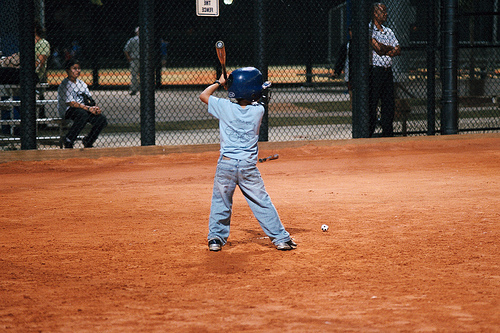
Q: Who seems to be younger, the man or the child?
A: The child is younger than the man.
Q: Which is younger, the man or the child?
A: The child is younger than the man.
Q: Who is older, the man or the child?
A: The man is older than the child.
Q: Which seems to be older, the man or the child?
A: The man is older than the child.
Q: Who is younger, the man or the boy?
A: The boy is younger than the man.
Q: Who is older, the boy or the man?
A: The man is older than the boy.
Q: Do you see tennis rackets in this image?
A: No, there are no tennis rackets.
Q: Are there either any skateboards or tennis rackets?
A: No, there are no tennis rackets or skateboards.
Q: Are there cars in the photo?
A: No, there are no cars.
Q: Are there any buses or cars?
A: No, there are no cars or buses.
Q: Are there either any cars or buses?
A: No, there are no cars or buses.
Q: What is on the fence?
A: The sign is on the fence.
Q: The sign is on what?
A: The sign is on the fence.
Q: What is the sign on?
A: The sign is on the fence.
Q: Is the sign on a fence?
A: Yes, the sign is on a fence.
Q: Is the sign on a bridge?
A: No, the sign is on a fence.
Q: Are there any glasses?
A: No, there are no glasses.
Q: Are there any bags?
A: No, there are no bags.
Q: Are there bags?
A: No, there are no bags.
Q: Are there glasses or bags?
A: No, there are no bags or glasses.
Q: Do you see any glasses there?
A: No, there are no glasses.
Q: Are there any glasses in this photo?
A: No, there are no glasses.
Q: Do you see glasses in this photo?
A: No, there are no glasses.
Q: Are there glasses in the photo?
A: No, there are no glasses.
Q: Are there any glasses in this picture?
A: No, there are no glasses.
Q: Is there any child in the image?
A: Yes, there is a child.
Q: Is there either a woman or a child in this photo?
A: Yes, there is a child.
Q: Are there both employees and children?
A: No, there is a child but no employees.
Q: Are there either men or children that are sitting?
A: Yes, the child is sitting.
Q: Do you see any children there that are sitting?
A: Yes, there is a child that is sitting.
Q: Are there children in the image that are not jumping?
A: Yes, there is a child that is sitting.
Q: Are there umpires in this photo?
A: No, there are no umpires.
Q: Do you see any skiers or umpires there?
A: No, there are no umpires or skiers.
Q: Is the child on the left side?
A: Yes, the child is on the left of the image.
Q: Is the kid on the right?
A: No, the kid is on the left of the image.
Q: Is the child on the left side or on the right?
A: The child is on the left of the image.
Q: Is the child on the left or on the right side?
A: The child is on the left of the image.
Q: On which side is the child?
A: The child is on the left of the image.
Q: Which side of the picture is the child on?
A: The child is on the left of the image.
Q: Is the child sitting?
A: Yes, the child is sitting.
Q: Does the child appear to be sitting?
A: Yes, the child is sitting.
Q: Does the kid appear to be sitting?
A: Yes, the kid is sitting.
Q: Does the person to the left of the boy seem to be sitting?
A: Yes, the kid is sitting.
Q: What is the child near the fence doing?
A: The kid is sitting.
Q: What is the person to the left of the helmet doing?
A: The kid is sitting.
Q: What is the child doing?
A: The kid is sitting.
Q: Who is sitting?
A: The kid is sitting.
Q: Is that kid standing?
A: No, the kid is sitting.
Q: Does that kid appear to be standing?
A: No, the kid is sitting.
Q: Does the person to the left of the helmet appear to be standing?
A: No, the kid is sitting.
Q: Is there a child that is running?
A: No, there is a child but he is sitting.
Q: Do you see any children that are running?
A: No, there is a child but he is sitting.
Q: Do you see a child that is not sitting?
A: No, there is a child but he is sitting.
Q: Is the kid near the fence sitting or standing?
A: The kid is sitting.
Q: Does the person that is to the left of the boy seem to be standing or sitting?
A: The kid is sitting.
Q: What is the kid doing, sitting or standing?
A: The kid is sitting.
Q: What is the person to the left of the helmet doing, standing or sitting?
A: The kid is sitting.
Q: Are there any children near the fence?
A: Yes, there is a child near the fence.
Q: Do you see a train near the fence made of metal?
A: No, there is a child near the fence.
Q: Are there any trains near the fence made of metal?
A: No, there is a child near the fence.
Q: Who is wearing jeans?
A: The kid is wearing jeans.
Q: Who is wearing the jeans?
A: The kid is wearing jeans.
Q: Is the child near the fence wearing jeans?
A: Yes, the kid is wearing jeans.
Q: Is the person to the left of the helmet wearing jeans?
A: Yes, the kid is wearing jeans.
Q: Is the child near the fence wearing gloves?
A: No, the kid is wearing jeans.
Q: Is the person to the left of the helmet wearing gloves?
A: No, the kid is wearing jeans.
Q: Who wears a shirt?
A: The child wears a shirt.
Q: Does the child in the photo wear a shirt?
A: Yes, the child wears a shirt.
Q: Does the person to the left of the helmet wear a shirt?
A: Yes, the child wears a shirt.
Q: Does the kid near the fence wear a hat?
A: No, the kid wears a shirt.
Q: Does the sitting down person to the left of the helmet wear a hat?
A: No, the kid wears a shirt.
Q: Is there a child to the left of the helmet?
A: Yes, there is a child to the left of the helmet.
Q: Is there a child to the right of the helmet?
A: No, the child is to the left of the helmet.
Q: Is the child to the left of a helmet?
A: Yes, the child is to the left of a helmet.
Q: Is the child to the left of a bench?
A: No, the child is to the left of a helmet.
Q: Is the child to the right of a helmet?
A: No, the child is to the left of a helmet.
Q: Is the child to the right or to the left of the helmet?
A: The child is to the left of the helmet.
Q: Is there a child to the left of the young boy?
A: Yes, there is a child to the left of the boy.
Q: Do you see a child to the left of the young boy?
A: Yes, there is a child to the left of the boy.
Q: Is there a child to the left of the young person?
A: Yes, there is a child to the left of the boy.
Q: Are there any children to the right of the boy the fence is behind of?
A: No, the child is to the left of the boy.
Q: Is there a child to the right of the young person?
A: No, the child is to the left of the boy.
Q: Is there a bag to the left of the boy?
A: No, there is a child to the left of the boy.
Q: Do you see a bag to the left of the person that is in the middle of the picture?
A: No, there is a child to the left of the boy.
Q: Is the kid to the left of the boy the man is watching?
A: Yes, the kid is to the left of the boy.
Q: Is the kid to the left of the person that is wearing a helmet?
A: Yes, the kid is to the left of the boy.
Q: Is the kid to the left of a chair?
A: No, the kid is to the left of the boy.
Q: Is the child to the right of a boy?
A: No, the child is to the left of a boy.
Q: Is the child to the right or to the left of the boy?
A: The child is to the left of the boy.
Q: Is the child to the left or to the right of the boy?
A: The child is to the left of the boy.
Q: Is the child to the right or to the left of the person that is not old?
A: The child is to the left of the boy.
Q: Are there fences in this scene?
A: Yes, there is a fence.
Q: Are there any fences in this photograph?
A: Yes, there is a fence.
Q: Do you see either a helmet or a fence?
A: Yes, there is a fence.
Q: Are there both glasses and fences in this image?
A: No, there is a fence but no glasses.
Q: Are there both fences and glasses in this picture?
A: No, there is a fence but no glasses.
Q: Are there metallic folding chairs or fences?
A: Yes, there is a metal fence.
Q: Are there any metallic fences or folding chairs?
A: Yes, there is a metal fence.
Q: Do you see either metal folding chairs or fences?
A: Yes, there is a metal fence.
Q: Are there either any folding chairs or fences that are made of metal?
A: Yes, the fence is made of metal.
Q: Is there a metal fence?
A: Yes, there is a metal fence.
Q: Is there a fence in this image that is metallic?
A: Yes, there is a fence that is metallic.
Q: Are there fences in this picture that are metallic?
A: Yes, there is a fence that is metallic.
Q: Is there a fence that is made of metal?
A: Yes, there is a fence that is made of metal.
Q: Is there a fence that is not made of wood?
A: Yes, there is a fence that is made of metal.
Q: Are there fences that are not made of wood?
A: Yes, there is a fence that is made of metal.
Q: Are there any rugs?
A: No, there are no rugs.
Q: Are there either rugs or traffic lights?
A: No, there are no rugs or traffic lights.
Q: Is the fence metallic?
A: Yes, the fence is metallic.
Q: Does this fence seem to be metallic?
A: Yes, the fence is metallic.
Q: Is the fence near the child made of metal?
A: Yes, the fence is made of metal.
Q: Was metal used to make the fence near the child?
A: Yes, the fence is made of metal.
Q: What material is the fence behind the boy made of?
A: The fence is made of metal.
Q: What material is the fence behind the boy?
A: The fence is made of metal.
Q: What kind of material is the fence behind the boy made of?
A: The fence is made of metal.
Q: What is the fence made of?
A: The fence is made of metal.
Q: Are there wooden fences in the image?
A: No, there is a fence but it is metallic.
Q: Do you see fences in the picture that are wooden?
A: No, there is a fence but it is metallic.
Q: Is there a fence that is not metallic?
A: No, there is a fence but it is metallic.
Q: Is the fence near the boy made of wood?
A: No, the fence is made of metal.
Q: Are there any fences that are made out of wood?
A: No, there is a fence but it is made of metal.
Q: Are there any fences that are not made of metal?
A: No, there is a fence but it is made of metal.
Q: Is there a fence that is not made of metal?
A: No, there is a fence but it is made of metal.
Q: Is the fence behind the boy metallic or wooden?
A: The fence is metallic.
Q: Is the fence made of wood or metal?
A: The fence is made of metal.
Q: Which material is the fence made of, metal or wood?
A: The fence is made of metal.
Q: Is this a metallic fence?
A: Yes, this is a metallic fence.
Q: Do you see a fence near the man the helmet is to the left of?
A: Yes, there is a fence near the man.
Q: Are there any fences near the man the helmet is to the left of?
A: Yes, there is a fence near the man.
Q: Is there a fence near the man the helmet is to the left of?
A: Yes, there is a fence near the man.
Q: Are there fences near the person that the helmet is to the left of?
A: Yes, there is a fence near the man.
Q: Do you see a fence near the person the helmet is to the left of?
A: Yes, there is a fence near the man.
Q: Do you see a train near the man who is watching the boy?
A: No, there is a fence near the man.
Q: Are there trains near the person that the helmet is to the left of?
A: No, there is a fence near the man.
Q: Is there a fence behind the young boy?
A: Yes, there is a fence behind the boy.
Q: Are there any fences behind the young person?
A: Yes, there is a fence behind the boy.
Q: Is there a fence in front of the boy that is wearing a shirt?
A: No, the fence is behind the boy.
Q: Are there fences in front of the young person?
A: No, the fence is behind the boy.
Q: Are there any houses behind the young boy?
A: No, there is a fence behind the boy.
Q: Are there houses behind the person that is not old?
A: No, there is a fence behind the boy.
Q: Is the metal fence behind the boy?
A: Yes, the fence is behind the boy.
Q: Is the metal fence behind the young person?
A: Yes, the fence is behind the boy.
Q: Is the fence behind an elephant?
A: No, the fence is behind the boy.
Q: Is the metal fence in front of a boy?
A: No, the fence is behind a boy.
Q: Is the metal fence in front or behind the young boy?
A: The fence is behind the boy.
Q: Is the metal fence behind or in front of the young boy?
A: The fence is behind the boy.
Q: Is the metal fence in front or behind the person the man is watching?
A: The fence is behind the boy.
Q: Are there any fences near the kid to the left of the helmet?
A: Yes, there is a fence near the child.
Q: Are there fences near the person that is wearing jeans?
A: Yes, there is a fence near the child.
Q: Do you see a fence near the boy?
A: Yes, there is a fence near the boy.